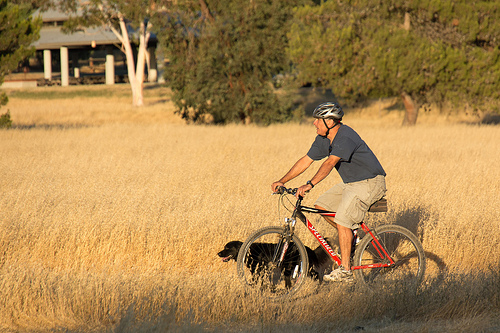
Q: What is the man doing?
A: Riding a bike.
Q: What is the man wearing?
A: A Helmet.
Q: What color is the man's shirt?
A: Blue.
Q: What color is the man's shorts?
A: Tan.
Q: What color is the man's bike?
A: Red.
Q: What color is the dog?
A: Black.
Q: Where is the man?
A: In a field.